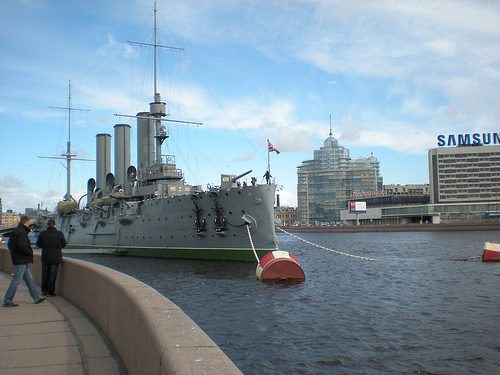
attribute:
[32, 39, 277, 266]
ship — gray., harbor., large.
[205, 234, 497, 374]
water. — dark., choppy.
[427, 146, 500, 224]
building — white., large., samsung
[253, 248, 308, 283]
buoy — red, white.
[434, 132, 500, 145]
sign — samsung.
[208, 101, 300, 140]
cloud — white.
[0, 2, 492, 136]
sky — blue.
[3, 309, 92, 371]
sidewalk — brick.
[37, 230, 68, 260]
jacket — black.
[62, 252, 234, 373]
ledge. — concrete.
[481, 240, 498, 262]
anchor — red, white.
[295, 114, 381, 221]
building — tall.